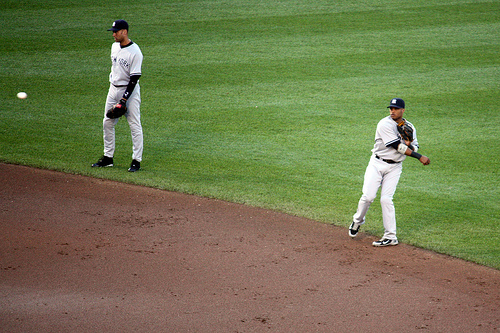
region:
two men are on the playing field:
[8, 4, 425, 276]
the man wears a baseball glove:
[398, 118, 416, 143]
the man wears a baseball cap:
[106, 20, 134, 35]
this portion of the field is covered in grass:
[170, 6, 457, 103]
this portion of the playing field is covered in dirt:
[21, 185, 358, 331]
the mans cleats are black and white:
[347, 210, 399, 247]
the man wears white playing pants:
[352, 158, 402, 235]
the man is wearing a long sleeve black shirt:
[119, 79, 135, 100]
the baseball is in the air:
[10, 82, 34, 108]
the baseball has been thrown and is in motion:
[7, 80, 37, 112]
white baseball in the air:
[16, 88, 31, 103]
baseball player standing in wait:
[94, 18, 144, 173]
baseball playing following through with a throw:
[333, 92, 433, 246]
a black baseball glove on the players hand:
[397, 119, 412, 142]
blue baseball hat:
[385, 95, 406, 110]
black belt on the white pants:
[375, 151, 402, 169]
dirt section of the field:
[0, 154, 498, 327]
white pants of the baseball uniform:
[348, 160, 411, 247]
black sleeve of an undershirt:
[119, 78, 136, 104]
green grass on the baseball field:
[1, 0, 497, 273]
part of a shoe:
[364, 233, 394, 243]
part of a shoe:
[133, 160, 163, 200]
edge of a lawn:
[261, 213, 263, 218]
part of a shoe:
[371, 233, 378, 253]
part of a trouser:
[389, 161, 402, 177]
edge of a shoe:
[383, 240, 385, 248]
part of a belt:
[398, 159, 405, 163]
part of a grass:
[298, 230, 308, 242]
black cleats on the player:
[88, 153, 143, 174]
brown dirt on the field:
[1, 162, 498, 330]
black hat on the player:
[103, 17, 130, 33]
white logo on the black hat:
[390, 97, 399, 104]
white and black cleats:
[348, 218, 403, 249]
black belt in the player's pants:
[370, 151, 405, 166]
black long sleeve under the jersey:
[120, 74, 140, 101]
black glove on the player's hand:
[396, 118, 414, 144]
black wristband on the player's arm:
[407, 150, 425, 163]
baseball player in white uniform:
[341, 95, 427, 246]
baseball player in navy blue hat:
[95, 15, 146, 175]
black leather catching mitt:
[105, 102, 132, 124]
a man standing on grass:
[65, 11, 148, 184]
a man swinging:
[305, 93, 435, 267]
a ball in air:
[11, 74, 33, 107]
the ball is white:
[9, 76, 36, 114]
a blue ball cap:
[373, 91, 419, 115]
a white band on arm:
[389, 142, 411, 158]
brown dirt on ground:
[31, 227, 252, 305]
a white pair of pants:
[344, 164, 408, 224]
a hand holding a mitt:
[86, 102, 133, 123]